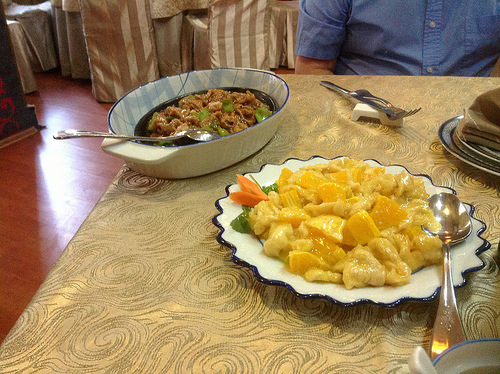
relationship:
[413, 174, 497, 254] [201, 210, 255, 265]
spoon on dish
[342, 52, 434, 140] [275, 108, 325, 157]
fork on table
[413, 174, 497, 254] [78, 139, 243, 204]
spoon in bowl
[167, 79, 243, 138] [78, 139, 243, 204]
meat in bowl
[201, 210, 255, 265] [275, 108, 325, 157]
dish on table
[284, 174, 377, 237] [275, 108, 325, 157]
cheese on table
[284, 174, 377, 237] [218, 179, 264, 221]
cheese and carrot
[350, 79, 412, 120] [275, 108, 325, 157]
knife on table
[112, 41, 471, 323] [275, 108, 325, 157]
food on table